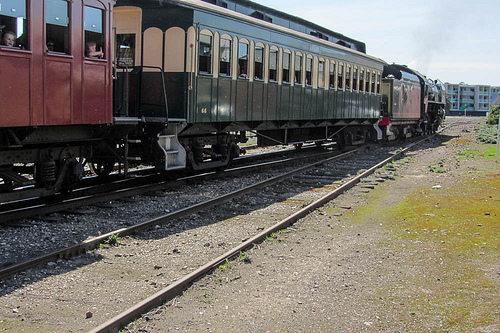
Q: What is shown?
A: A train.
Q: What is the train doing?
A: Merging from one track to another.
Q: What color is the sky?
A: Blue and white.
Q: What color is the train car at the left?
A: Red.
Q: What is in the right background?
A: A building.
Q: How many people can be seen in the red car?
A: Two.